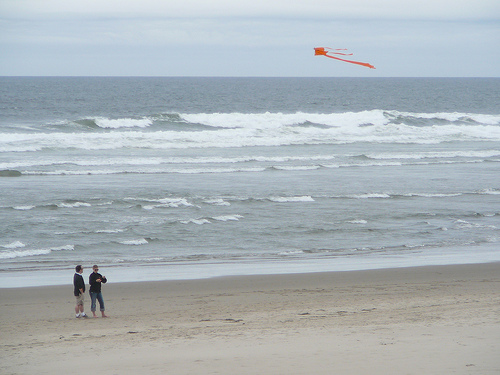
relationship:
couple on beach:
[73, 265, 109, 319] [2, 260, 498, 373]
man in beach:
[74, 265, 89, 320] [1, 76, 496, 374]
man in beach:
[74, 265, 89, 320] [2, 260, 498, 373]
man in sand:
[74, 265, 89, 320] [0, 258, 492, 373]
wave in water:
[0, 109, 500, 271] [3, 79, 492, 261]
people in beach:
[90, 255, 116, 319] [9, 155, 493, 374]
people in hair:
[89, 265, 110, 318] [93, 264, 101, 271]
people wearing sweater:
[89, 265, 110, 318] [87, 270, 107, 292]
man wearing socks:
[74, 265, 89, 320] [71, 307, 89, 314]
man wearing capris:
[74, 265, 89, 320] [89, 291, 105, 312]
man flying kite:
[70, 260, 85, 317] [308, 43, 378, 73]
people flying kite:
[89, 265, 110, 318] [308, 43, 378, 73]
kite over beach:
[315, 45, 375, 68] [1, 76, 496, 374]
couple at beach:
[73, 265, 109, 319] [0, 112, 497, 368]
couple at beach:
[71, 264, 92, 315] [0, 112, 497, 368]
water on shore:
[0, 76, 500, 284] [209, 273, 444, 367]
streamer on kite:
[325, 46, 348, 52] [314, 46, 376, 70]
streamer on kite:
[325, 49, 352, 56] [314, 46, 376, 70]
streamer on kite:
[324, 54, 375, 68] [314, 46, 376, 70]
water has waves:
[0, 76, 500, 284] [1, 110, 497, 177]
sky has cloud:
[0, 0, 498, 80] [3, 0, 499, 45]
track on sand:
[359, 302, 376, 316] [363, 266, 485, 371]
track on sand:
[296, 307, 311, 317] [363, 266, 485, 371]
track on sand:
[220, 313, 243, 324] [363, 266, 485, 371]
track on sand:
[198, 314, 212, 320] [363, 266, 485, 371]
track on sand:
[125, 328, 136, 336] [363, 266, 485, 371]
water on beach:
[0, 241, 500, 288] [2, 260, 498, 373]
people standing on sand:
[89, 265, 110, 318] [66, 314, 127, 337]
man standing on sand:
[74, 265, 89, 320] [66, 314, 127, 337]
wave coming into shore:
[0, 109, 492, 271] [44, 228, 491, 317]